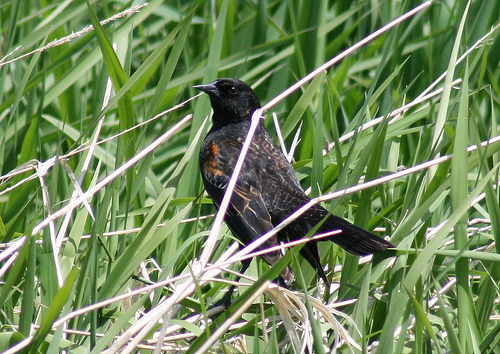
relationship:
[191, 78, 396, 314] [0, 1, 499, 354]
bird in grass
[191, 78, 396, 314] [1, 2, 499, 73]
bird looking in air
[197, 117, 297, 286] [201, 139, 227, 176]
feathers have orange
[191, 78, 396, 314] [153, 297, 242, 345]
bird on branch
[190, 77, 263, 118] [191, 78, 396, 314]
head of bird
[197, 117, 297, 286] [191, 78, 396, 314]
feathers are on bird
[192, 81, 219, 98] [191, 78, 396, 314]
beak of bird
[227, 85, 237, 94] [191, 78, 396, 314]
eye of bird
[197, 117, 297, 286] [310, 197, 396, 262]
feathers are on tail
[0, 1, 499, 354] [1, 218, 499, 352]
grass on ground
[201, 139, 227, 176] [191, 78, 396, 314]
orange on bird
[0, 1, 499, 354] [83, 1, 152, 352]
grass of grass